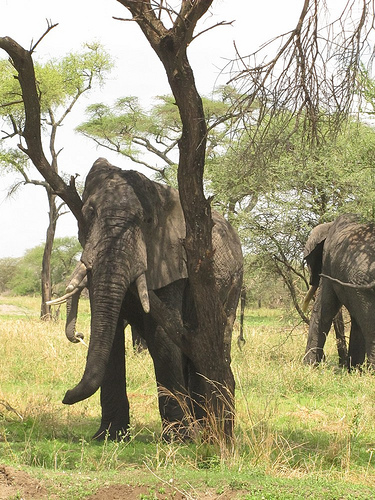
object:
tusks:
[42, 288, 83, 309]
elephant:
[59, 153, 249, 447]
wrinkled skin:
[216, 236, 240, 276]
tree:
[113, 0, 230, 439]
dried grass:
[296, 381, 367, 410]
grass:
[0, 438, 373, 499]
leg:
[350, 279, 375, 370]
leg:
[298, 271, 346, 367]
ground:
[0, 452, 184, 500]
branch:
[318, 0, 374, 150]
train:
[63, 144, 178, 308]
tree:
[213, 96, 372, 372]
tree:
[0, 40, 117, 320]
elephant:
[299, 215, 375, 378]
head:
[59, 155, 163, 412]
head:
[299, 222, 326, 326]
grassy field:
[0, 357, 60, 489]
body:
[323, 209, 374, 308]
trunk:
[60, 267, 134, 408]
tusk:
[132, 272, 155, 317]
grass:
[0, 324, 61, 437]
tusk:
[62, 260, 88, 296]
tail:
[315, 269, 374, 292]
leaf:
[72, 98, 120, 147]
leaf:
[43, 76, 64, 99]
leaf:
[277, 158, 298, 185]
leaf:
[57, 57, 80, 88]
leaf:
[359, 143, 375, 169]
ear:
[301, 219, 335, 261]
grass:
[273, 411, 375, 460]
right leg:
[341, 316, 366, 371]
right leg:
[89, 314, 136, 443]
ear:
[146, 184, 190, 295]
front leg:
[136, 275, 199, 446]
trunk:
[61, 262, 85, 353]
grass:
[238, 341, 300, 500]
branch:
[230, 0, 329, 162]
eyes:
[82, 202, 99, 224]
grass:
[0, 292, 35, 323]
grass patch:
[254, 367, 375, 500]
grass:
[246, 292, 299, 386]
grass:
[131, 379, 153, 456]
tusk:
[297, 280, 318, 320]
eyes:
[127, 208, 146, 233]